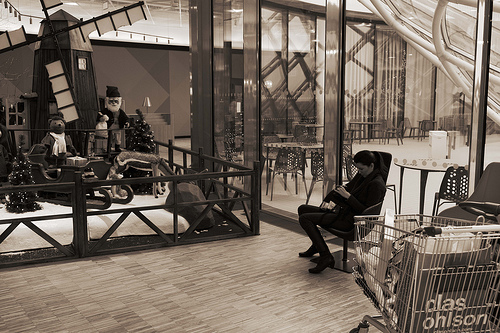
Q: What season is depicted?
A: Winter.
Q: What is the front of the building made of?
A: Glass.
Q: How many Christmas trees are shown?
A: 2.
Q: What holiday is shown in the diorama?
A: Christmas.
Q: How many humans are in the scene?
A: 1.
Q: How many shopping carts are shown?
A: 1.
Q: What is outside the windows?
A: Tables and chairs.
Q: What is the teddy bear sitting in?
A: Sleigh.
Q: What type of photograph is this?
A: Black and white.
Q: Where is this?
A: A department store.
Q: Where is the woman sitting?
A: On the chair.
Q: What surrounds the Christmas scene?
A: A fence.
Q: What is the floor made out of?
A: Wood.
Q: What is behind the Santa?
A: A windmill.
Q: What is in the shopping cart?
A: Bags.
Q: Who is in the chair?
A: A woman.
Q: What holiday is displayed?
A: Christmas.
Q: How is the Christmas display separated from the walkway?
A: Fence.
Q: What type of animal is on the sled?
A: Bear.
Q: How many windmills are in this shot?
A: One.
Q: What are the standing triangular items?
A: Christmas trees.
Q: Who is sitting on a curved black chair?
A: A brunette woman, in black.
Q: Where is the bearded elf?
A: Standing, to the right of the windmill.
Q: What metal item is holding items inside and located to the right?
A: A supermarket basket.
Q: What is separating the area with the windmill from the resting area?
A: A low fence.